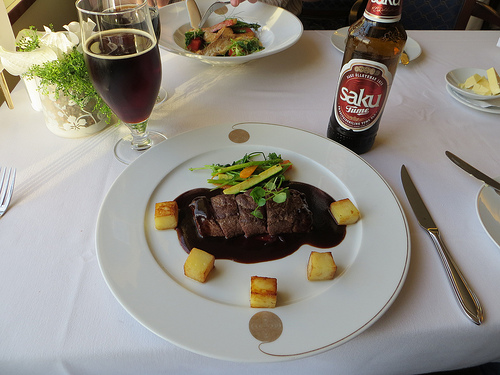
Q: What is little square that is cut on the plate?
A: Pineapples.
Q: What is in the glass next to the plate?
A: A glass full of wine.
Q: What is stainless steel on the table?
A: A silver knife.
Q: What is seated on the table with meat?
A: A white and gold dinner plate.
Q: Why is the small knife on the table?
A: To cut meat.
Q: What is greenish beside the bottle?
A: A plant.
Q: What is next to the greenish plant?
A: Medium sized glass full of dark beer.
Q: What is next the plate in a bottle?
A: Brown glass bottle of beer.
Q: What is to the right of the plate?
A: A knife.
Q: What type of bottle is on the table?
A: A Saku beer bottle.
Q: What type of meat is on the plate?
A: A steak.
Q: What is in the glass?
A: A dark colored beverage.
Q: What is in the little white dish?
A: Butter.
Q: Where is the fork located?
A: To the far left of the steak plate.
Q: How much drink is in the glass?
A: Half full.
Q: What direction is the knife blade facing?
A: Towards the plate.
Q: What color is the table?
A: White.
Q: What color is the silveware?
A: SIlver.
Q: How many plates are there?
A: 1.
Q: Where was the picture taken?
A: At a table.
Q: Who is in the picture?
A: No one.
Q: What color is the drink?
A: Brown.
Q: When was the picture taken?
A: Before the food was eaten.